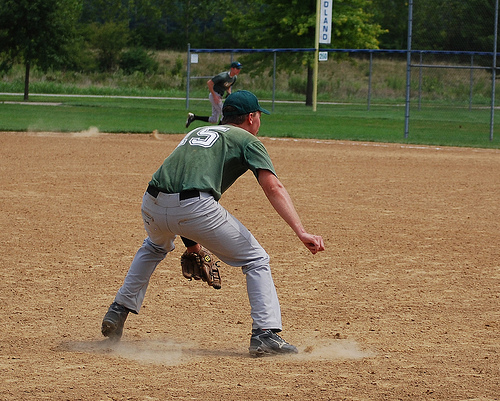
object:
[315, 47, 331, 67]
sign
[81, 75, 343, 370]
player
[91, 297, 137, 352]
shoe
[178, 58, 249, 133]
uniform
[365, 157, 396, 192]
ground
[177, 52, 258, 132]
man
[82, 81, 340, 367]
man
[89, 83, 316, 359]
baseball uniform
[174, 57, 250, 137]
player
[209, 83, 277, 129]
hat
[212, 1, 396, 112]
trees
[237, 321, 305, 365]
shoe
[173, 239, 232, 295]
baseball mit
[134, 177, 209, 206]
belt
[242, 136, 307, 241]
arm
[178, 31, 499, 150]
fence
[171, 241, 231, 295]
baseball glove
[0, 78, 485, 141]
field